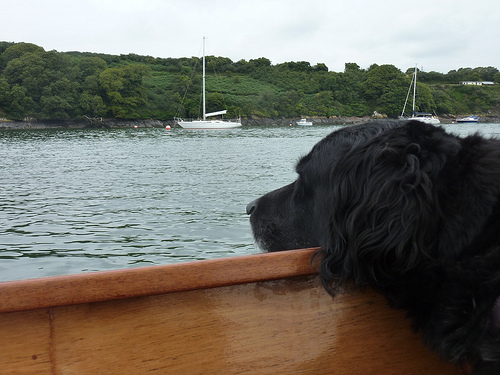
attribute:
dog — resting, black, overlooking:
[239, 115, 497, 365]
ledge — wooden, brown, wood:
[2, 245, 333, 314]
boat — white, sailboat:
[5, 242, 464, 374]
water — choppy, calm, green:
[0, 124, 498, 278]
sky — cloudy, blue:
[1, 2, 500, 64]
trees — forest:
[5, 46, 154, 119]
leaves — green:
[60, 89, 68, 90]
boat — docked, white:
[176, 31, 246, 128]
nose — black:
[242, 194, 267, 222]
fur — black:
[344, 161, 428, 242]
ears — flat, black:
[323, 144, 443, 289]